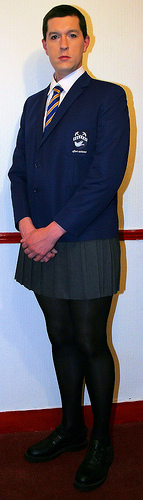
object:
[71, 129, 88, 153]
patch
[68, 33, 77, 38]
eye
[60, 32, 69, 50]
nose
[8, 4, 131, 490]
man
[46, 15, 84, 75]
face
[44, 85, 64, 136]
tie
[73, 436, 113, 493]
shoe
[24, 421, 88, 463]
shoe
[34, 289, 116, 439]
pantyhose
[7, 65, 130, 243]
blazer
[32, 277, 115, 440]
legs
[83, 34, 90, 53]
ear